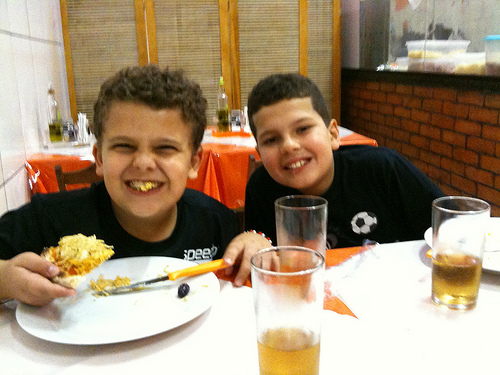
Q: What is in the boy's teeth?
A: Corn.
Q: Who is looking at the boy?
A: The photographer.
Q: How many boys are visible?
A: Two.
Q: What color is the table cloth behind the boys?
A: Orange.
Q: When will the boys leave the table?
A: After they are done eating.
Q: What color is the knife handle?
A: Yellow.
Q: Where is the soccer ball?
A: On the shirt of the boy on the right.